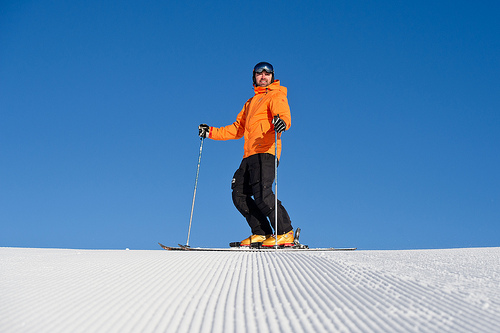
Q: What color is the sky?
A: Blue.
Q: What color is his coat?
A: Orange.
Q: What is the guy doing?
A: Skiing.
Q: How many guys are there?
A: One.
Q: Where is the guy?
A: Top of a ski slope.